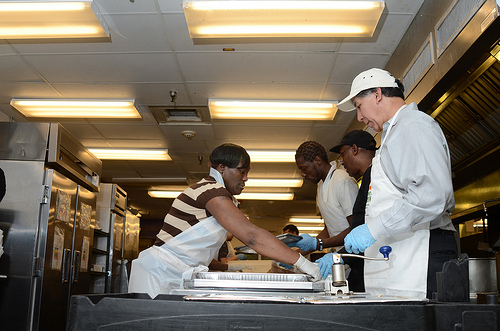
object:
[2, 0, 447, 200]
ceiling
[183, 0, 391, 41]
bulbs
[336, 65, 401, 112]
cap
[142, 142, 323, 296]
people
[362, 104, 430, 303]
apron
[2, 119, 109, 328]
fridges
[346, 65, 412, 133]
head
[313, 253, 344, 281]
gloves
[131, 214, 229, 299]
apron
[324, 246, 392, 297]
can opener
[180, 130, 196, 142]
fire alarm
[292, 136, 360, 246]
worker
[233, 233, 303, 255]
tray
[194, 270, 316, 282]
container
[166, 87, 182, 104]
sprinkler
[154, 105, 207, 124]
air vents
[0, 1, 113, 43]
light fixture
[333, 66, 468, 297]
man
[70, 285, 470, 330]
table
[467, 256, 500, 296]
pot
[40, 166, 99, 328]
doors